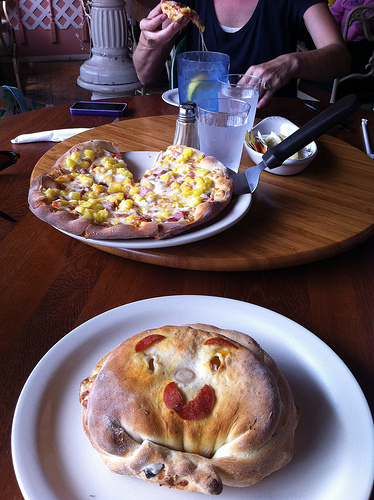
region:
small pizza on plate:
[25, 119, 239, 230]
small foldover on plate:
[91, 304, 289, 471]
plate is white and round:
[67, 316, 323, 498]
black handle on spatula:
[205, 97, 350, 188]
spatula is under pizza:
[219, 75, 358, 201]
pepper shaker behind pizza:
[179, 98, 204, 164]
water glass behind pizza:
[190, 81, 254, 172]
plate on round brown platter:
[73, 143, 240, 232]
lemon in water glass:
[156, 59, 249, 132]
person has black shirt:
[160, 6, 327, 94]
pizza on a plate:
[9, 49, 355, 295]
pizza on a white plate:
[24, 119, 342, 308]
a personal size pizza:
[23, 78, 317, 309]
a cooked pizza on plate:
[34, 112, 246, 278]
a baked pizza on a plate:
[14, 102, 320, 323]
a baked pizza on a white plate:
[32, 83, 322, 346]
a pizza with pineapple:
[25, 120, 348, 323]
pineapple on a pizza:
[45, 100, 301, 281]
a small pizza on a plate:
[9, 120, 357, 328]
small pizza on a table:
[10, 81, 353, 285]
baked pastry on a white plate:
[1, 266, 372, 498]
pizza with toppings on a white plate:
[25, 162, 225, 251]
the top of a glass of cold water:
[198, 94, 247, 148]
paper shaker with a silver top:
[173, 96, 199, 143]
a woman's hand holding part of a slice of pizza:
[129, 1, 205, 46]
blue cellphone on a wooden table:
[67, 99, 133, 116]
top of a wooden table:
[20, 250, 97, 302]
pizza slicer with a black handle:
[229, 86, 372, 201]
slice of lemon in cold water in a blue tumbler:
[185, 68, 215, 99]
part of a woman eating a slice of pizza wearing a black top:
[136, 0, 362, 59]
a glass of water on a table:
[195, 97, 251, 176]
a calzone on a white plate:
[79, 319, 296, 493]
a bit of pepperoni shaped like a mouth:
[163, 381, 215, 418]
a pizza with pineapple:
[31, 138, 233, 242]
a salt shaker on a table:
[172, 99, 199, 150]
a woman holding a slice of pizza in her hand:
[133, 1, 205, 46]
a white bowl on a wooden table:
[243, 113, 317, 176]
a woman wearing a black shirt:
[161, 0, 319, 101]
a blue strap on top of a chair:
[2, 81, 28, 114]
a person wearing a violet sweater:
[330, 2, 372, 40]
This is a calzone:
[77, 309, 213, 459]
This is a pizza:
[116, 192, 238, 279]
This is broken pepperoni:
[139, 391, 241, 463]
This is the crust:
[79, 377, 132, 451]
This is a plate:
[54, 461, 86, 492]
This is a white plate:
[10, 424, 98, 487]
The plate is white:
[88, 481, 101, 493]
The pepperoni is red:
[170, 375, 230, 414]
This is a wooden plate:
[298, 240, 336, 296]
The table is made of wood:
[324, 295, 345, 343]